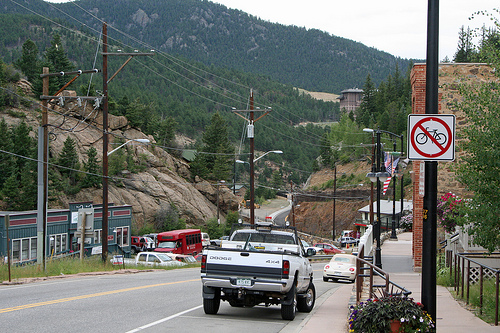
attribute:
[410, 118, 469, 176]
sign — see, here, red, white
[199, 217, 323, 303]
truck — pickup, four wheel drive, white, red, here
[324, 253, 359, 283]
car — convertible, small, white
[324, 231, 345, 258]
van — red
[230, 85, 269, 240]
pole — brown, here, black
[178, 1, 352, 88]
mountain — covered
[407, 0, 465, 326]
pole — black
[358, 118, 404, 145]
light — hanging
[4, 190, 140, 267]
building — red, green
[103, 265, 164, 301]
road — here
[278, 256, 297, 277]
tail light — red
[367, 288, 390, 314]
flower — potted, hanging, pink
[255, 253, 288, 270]
number — silver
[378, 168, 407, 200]
flag — american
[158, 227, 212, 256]
bus — red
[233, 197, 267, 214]
tractor — yellow